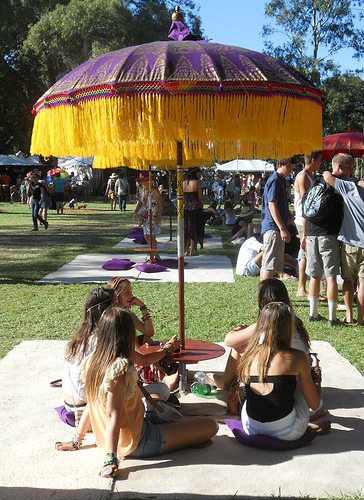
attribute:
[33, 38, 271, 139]
umbrella — multicolored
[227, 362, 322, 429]
black top — sleeveless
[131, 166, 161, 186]
hat — red, a cowboy hat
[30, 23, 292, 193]
umbrella — elaborate, sun-shading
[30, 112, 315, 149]
fringe — golden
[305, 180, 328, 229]
design — graphic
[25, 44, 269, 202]
umbrella — sun-shading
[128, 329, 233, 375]
umbrella platform — for umbrellas, small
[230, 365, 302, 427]
top — black, a halter top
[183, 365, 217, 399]
bottles — empty, soda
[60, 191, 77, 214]
child — small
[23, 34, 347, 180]
umbrella — gold, purple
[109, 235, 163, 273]
pillows — purple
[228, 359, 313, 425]
top — black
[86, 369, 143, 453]
top — light, orange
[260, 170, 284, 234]
shirt — blue 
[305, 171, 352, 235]
shirt — black 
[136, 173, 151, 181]
hat — red  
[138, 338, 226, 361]
table — small 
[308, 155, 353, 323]
man — young 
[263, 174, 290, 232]
shirt — blue 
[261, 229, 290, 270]
shorts — grey 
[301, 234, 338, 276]
shorts — grey 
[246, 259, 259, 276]
shorts — blue 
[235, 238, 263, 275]
shirt — white 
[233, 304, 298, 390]
hair — brown 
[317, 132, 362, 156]
umbrella — red 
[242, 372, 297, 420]
top — black 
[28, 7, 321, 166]
umbrella — purple and yellow, richly colored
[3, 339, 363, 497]
blanket — white 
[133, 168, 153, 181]
hat — red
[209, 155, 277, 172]
shelter — outdoor, pavilion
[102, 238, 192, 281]
pillows — square, purple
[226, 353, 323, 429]
top — black, cutout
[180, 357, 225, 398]
bottles — empty, plastic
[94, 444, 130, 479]
bracelets — green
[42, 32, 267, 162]
umbrella — large, purple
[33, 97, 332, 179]
fringe — bright yellow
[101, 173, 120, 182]
hat — tan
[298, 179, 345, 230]
backpack — black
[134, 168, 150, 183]
cowboy hat — pink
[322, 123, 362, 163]
umbrella — red, gold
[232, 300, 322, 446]
woman — young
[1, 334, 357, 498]
slab — concrete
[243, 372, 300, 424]
shirt — black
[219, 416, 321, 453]
pillow — purple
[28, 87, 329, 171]
tassels — yellow, bright yellow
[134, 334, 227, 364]
table — small, round, wooden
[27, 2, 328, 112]
umbrella — purple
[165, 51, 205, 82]
designs — metallic, gold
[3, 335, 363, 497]
pad — concrete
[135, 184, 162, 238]
dress — flowered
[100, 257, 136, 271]
pillow — square, purple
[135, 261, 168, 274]
pillow — square, purple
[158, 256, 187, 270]
pillow — square, purple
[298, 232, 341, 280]
shorts — khaki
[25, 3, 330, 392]
umbrella — big, purple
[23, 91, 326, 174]
fringes — yellow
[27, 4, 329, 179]
umbrella — purple, yellow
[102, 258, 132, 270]
cushion — purple